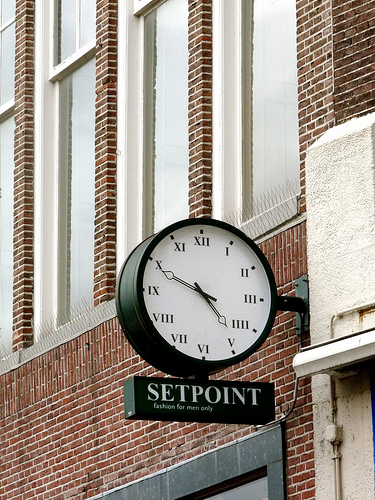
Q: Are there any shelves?
A: No, there are no shelves.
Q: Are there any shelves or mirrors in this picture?
A: No, there are no shelves or mirrors.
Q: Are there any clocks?
A: Yes, there is a clock.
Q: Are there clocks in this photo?
A: Yes, there is a clock.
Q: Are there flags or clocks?
A: Yes, there is a clock.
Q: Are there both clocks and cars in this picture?
A: No, there is a clock but no cars.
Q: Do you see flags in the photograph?
A: No, there are no flags.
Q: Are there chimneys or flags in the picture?
A: No, there are no flags or chimneys.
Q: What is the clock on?
A: The clock is on the sign.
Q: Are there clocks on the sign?
A: Yes, there is a clock on the sign.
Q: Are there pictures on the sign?
A: No, there is a clock on the sign.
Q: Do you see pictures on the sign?
A: No, there is a clock on the sign.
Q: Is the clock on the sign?
A: Yes, the clock is on the sign.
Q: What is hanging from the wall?
A: The clock is hanging from the wall.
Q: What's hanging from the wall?
A: The clock is hanging from the wall.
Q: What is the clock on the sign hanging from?
A: The clock is hanging from the wall.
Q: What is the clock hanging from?
A: The clock is hanging from the wall.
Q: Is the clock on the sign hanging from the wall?
A: Yes, the clock is hanging from the wall.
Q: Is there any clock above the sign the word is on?
A: Yes, there is a clock above the sign.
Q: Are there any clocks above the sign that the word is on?
A: Yes, there is a clock above the sign.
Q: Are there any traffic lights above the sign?
A: No, there is a clock above the sign.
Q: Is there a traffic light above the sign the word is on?
A: No, there is a clock above the sign.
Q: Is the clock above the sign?
A: Yes, the clock is above the sign.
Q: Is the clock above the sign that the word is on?
A: Yes, the clock is above the sign.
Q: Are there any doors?
A: Yes, there is a door.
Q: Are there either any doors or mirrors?
A: Yes, there is a door.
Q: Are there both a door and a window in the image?
A: Yes, there are both a door and a window.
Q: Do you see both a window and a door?
A: Yes, there are both a door and a window.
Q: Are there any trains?
A: No, there are no trains.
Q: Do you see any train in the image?
A: No, there are no trains.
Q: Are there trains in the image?
A: No, there are no trains.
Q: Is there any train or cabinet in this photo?
A: No, there are no trains or cabinets.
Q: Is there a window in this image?
A: Yes, there is a window.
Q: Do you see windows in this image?
A: Yes, there is a window.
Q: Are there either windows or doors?
A: Yes, there is a window.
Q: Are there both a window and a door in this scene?
A: Yes, there are both a window and a door.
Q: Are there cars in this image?
A: No, there are no cars.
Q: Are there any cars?
A: No, there are no cars.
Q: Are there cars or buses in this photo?
A: No, there are no cars or buses.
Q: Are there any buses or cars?
A: No, there are no cars or buses.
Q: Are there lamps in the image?
A: No, there are no lamps.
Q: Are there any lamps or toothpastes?
A: No, there are no lamps or toothpastes.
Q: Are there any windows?
A: Yes, there is a window.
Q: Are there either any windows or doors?
A: Yes, there is a window.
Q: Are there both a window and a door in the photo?
A: Yes, there are both a window and a door.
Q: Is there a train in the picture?
A: No, there are no trains.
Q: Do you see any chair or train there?
A: No, there are no trains or chairs.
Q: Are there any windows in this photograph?
A: Yes, there is a window.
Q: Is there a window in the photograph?
A: Yes, there is a window.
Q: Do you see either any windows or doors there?
A: Yes, there is a window.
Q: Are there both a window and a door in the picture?
A: Yes, there are both a window and a door.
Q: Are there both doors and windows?
A: Yes, there are both a window and a door.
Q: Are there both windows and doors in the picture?
A: Yes, there are both a window and a door.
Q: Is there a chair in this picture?
A: No, there are no chairs.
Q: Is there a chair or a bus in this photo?
A: No, there are no chairs or buses.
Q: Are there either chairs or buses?
A: No, there are no chairs or buses.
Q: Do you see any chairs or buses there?
A: No, there are no chairs or buses.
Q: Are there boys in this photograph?
A: No, there are no boys.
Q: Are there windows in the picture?
A: Yes, there are windows.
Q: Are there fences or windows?
A: Yes, there are windows.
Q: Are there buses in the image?
A: No, there are no buses.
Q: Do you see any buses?
A: No, there are no buses.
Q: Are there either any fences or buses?
A: No, there are no buses or fences.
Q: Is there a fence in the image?
A: No, there are no fences.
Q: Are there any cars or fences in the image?
A: No, there are no fences or cars.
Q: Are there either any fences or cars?
A: No, there are no fences or cars.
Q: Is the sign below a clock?
A: Yes, the sign is below a clock.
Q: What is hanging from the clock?
A: The sign is hanging from the clock.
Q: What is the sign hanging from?
A: The sign is hanging from the clock.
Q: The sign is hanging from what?
A: The sign is hanging from the clock.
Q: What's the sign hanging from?
A: The sign is hanging from the clock.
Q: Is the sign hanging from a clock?
A: Yes, the sign is hanging from a clock.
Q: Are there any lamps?
A: No, there are no lamps.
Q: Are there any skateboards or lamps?
A: No, there are no lamps or skateboards.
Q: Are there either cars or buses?
A: No, there are no cars or buses.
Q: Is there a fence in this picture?
A: No, there are no fences.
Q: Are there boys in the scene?
A: No, there are no boys.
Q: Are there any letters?
A: Yes, there are letters.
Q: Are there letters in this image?
A: Yes, there are letters.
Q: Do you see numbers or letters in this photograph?
A: Yes, there are letters.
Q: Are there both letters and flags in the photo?
A: No, there are letters but no flags.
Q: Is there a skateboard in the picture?
A: No, there are no skateboards.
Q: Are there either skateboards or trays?
A: No, there are no skateboards or trays.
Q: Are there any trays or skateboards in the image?
A: No, there are no skateboards or trays.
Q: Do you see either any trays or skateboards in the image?
A: No, there are no skateboards or trays.